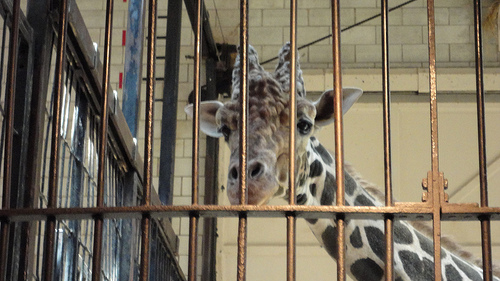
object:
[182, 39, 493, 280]
giraffe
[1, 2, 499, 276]
cage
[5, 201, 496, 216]
bar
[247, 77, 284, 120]
brown spots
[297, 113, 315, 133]
eye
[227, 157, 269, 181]
nose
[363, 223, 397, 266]
black spot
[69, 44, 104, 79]
hinges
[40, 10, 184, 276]
fence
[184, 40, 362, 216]
head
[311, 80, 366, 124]
ear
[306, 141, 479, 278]
long neck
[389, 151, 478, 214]
bracket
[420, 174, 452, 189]
metal bolts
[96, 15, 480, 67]
cinderblock wall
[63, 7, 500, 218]
background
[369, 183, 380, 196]
brown hairs